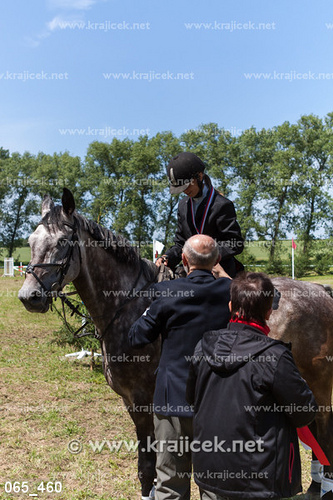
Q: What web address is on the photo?
A: www.krajicek.net.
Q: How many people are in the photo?
A: Three.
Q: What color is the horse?
A: Brown and white.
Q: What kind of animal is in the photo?
A: Horse.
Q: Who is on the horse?
A: Jockey.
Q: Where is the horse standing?
A: Field.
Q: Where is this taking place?
A: Near horse.